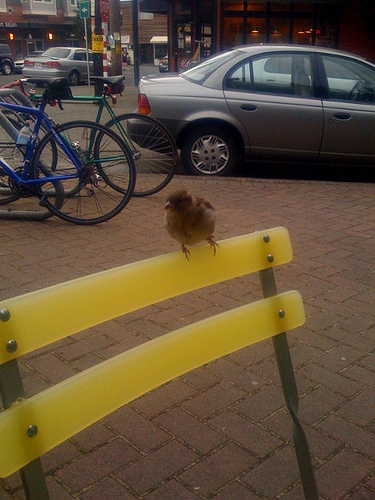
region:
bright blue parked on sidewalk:
[6, 74, 143, 225]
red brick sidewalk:
[8, 183, 373, 491]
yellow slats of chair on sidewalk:
[5, 221, 316, 473]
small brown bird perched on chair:
[157, 187, 227, 270]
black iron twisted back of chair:
[267, 331, 319, 491]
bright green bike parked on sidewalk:
[22, 71, 179, 204]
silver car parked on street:
[128, 51, 368, 185]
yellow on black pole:
[89, 33, 106, 52]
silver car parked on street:
[23, 43, 119, 86]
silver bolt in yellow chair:
[27, 425, 38, 437]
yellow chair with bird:
[3, 219, 323, 491]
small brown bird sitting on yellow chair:
[157, 184, 231, 260]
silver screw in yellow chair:
[19, 413, 49, 444]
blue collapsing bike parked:
[9, 65, 99, 228]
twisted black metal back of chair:
[257, 270, 330, 494]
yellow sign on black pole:
[92, 31, 105, 55]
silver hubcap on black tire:
[189, 139, 225, 170]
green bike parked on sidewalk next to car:
[18, 73, 172, 195]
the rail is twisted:
[262, 279, 319, 497]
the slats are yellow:
[1, 257, 301, 403]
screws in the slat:
[2, 308, 20, 350]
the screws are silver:
[1, 308, 20, 364]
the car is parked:
[148, 56, 373, 179]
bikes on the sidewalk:
[9, 82, 155, 223]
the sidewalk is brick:
[59, 337, 354, 482]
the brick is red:
[66, 171, 298, 221]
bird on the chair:
[148, 183, 235, 258]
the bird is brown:
[167, 189, 220, 257]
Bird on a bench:
[157, 180, 233, 270]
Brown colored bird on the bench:
[142, 179, 253, 295]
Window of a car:
[223, 45, 318, 107]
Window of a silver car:
[219, 46, 322, 117]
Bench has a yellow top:
[25, 261, 176, 419]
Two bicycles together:
[1, 61, 153, 237]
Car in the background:
[20, 38, 95, 80]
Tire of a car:
[180, 118, 243, 181]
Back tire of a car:
[179, 115, 243, 184]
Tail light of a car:
[130, 88, 154, 116]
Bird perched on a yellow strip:
[162, 189, 220, 262]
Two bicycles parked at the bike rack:
[0, 74, 181, 226]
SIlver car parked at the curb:
[126, 45, 373, 179]